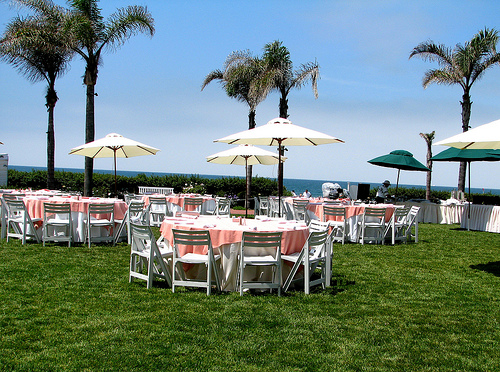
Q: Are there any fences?
A: No, there are no fences.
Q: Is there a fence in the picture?
A: No, there are no fences.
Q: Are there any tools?
A: No, there are no tools.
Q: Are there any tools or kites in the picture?
A: No, there are no tools or kites.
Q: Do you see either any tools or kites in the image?
A: No, there are no tools or kites.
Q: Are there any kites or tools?
A: No, there are no tools or kites.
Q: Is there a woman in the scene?
A: No, there are no women.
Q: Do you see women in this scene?
A: No, there are no women.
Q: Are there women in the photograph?
A: No, there are no women.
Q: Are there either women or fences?
A: No, there are no women or fences.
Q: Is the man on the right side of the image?
A: Yes, the man is on the right of the image.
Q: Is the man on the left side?
A: No, the man is on the right of the image.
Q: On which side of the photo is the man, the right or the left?
A: The man is on the right of the image.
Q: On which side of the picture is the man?
A: The man is on the right of the image.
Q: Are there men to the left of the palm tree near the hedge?
A: No, the man is to the right of the palm tree.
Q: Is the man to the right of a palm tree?
A: Yes, the man is to the right of a palm tree.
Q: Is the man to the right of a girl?
A: No, the man is to the right of a palm tree.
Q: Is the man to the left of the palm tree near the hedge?
A: No, the man is to the right of the palm tree.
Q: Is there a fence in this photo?
A: No, there are no fences.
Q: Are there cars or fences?
A: No, there are no fences or cars.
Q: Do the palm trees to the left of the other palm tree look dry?
A: Yes, the palm trees are dry.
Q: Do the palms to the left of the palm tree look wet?
A: No, the palms are dry.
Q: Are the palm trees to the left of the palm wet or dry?
A: The palms are dry.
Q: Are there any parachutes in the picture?
A: No, there are no parachutes.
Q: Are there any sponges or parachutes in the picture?
A: No, there are no parachutes or sponges.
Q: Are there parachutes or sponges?
A: No, there are no parachutes or sponges.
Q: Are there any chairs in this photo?
A: Yes, there is a chair.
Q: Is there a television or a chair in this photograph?
A: Yes, there is a chair.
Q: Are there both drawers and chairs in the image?
A: No, there is a chair but no drawers.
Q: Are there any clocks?
A: No, there are no clocks.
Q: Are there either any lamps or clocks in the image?
A: No, there are no clocks or lamps.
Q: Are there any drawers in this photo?
A: No, there are no drawers.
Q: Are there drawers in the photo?
A: No, there are no drawers.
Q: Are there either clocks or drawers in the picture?
A: No, there are no drawers or clocks.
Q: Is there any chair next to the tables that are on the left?
A: Yes, there are chairs next to the tables.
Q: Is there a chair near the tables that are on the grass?
A: Yes, there are chairs near the tables.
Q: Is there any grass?
A: Yes, there is grass.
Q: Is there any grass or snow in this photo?
A: Yes, there is grass.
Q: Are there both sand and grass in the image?
A: No, there is grass but no sand.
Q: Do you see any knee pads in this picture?
A: No, there are no knee pads.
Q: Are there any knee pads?
A: No, there are no knee pads.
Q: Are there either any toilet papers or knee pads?
A: No, there are no knee pads or toilet papers.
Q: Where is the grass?
A: The grass is on the ground.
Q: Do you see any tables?
A: Yes, there is a table.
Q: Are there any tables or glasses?
A: Yes, there is a table.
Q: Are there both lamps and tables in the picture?
A: No, there is a table but no lamps.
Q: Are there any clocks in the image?
A: No, there are no clocks.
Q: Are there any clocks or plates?
A: No, there are no clocks or plates.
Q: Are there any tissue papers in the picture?
A: No, there are no tissue papers.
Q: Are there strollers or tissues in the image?
A: No, there are no tissues or strollers.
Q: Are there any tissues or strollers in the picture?
A: No, there are no tissues or strollers.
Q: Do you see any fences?
A: No, there are no fences.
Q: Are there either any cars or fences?
A: No, there are no fences or cars.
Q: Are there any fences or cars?
A: No, there are no fences or cars.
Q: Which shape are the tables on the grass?
A: The tables are round.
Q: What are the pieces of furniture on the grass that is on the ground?
A: The pieces of furniture are tables.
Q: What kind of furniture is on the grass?
A: The pieces of furniture are tables.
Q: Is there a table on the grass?
A: Yes, there are tables on the grass.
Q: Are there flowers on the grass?
A: No, there are tables on the grass.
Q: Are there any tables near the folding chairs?
A: Yes, there are tables near the chairs.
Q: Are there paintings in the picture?
A: No, there are no paintings.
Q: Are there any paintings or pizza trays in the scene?
A: No, there are no paintings or pizza trays.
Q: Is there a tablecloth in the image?
A: Yes, there is a tablecloth.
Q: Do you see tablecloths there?
A: Yes, there is a tablecloth.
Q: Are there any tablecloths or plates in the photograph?
A: Yes, there is a tablecloth.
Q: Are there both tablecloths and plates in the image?
A: No, there is a tablecloth but no plates.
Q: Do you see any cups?
A: No, there are no cups.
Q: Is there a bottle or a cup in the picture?
A: No, there are no cups or bottles.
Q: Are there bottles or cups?
A: No, there are no cups or bottles.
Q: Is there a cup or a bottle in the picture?
A: No, there are no cups or bottles.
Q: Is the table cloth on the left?
A: No, the table cloth is on the right of the image.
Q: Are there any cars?
A: No, there are no cars.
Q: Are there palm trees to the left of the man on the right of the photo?
A: Yes, there is a palm tree to the left of the man.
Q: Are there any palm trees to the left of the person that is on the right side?
A: Yes, there is a palm tree to the left of the man.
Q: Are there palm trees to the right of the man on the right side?
A: No, the palm tree is to the left of the man.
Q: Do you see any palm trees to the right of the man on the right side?
A: No, the palm tree is to the left of the man.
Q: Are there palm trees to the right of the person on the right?
A: No, the palm tree is to the left of the man.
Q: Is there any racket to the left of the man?
A: No, there is a palm tree to the left of the man.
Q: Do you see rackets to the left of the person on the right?
A: No, there is a palm tree to the left of the man.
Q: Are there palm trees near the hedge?
A: Yes, there is a palm tree near the hedge.